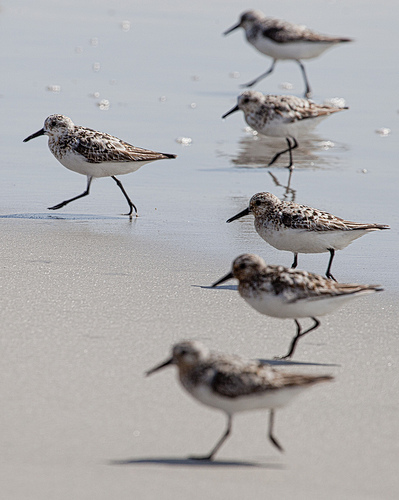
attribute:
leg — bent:
[35, 175, 105, 222]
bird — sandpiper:
[55, 99, 175, 240]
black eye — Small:
[46, 117, 60, 130]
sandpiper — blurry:
[137, 329, 345, 468]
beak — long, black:
[225, 206, 249, 222]